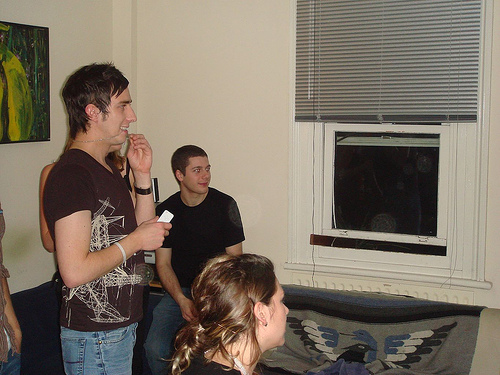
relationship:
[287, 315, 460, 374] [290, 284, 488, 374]
bird on top of blanket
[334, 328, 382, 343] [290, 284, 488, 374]
snake on top of blanket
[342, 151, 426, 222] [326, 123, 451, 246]
dark night outside of window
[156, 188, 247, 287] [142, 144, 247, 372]
shirt on man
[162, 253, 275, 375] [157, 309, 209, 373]
hair tied into a ponytail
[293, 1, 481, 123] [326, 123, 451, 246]
blinds on window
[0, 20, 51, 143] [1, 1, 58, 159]
painting hanging on wall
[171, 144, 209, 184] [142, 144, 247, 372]
hair on man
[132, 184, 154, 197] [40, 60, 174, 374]
wrist watch on man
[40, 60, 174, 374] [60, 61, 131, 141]
person has hair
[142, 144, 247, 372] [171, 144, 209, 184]
person has hair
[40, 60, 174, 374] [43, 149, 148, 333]
person wearing a t-shirt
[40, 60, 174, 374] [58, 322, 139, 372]
person wearing jeans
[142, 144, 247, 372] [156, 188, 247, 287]
person wearing a shirt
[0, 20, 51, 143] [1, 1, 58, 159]
picture hanging on wall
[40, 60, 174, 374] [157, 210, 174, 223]
man playing video game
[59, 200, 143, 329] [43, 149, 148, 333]
designs on side of shirt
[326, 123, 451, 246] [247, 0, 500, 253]
small window in wall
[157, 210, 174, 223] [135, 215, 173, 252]
video game in hand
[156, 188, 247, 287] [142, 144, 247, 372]
t-shirt on boy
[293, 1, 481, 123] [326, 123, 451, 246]
raised blinds on window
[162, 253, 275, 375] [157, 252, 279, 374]
hair on girl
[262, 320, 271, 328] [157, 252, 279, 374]
small earring on blonde girl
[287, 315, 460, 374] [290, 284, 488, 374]
bird design on top of blanket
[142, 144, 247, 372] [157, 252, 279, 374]
man and a woman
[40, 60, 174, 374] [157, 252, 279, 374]
man and a woman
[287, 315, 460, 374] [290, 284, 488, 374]
eagle on top of blanket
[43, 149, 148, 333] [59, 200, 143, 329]
shirt has a wire design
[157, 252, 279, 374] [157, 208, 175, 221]
person watching a video game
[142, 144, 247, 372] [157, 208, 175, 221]
person watching a video game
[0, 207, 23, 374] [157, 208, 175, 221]
person watching a video game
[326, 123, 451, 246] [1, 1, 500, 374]
window in room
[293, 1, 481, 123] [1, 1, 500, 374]
window blind in room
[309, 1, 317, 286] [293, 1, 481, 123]
cord on a window blinds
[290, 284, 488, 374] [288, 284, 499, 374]
blanket on top of bed